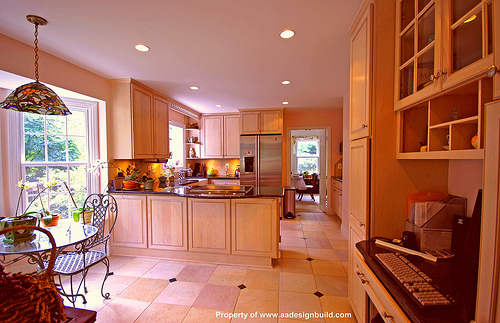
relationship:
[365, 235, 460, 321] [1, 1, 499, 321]
desk in kitchen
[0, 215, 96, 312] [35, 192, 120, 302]
table with chair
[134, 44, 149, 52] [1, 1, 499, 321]
kitchen lighting in kitchen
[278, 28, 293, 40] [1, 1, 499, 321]
kitchen lighting in kitchen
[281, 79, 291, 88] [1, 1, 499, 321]
lighting in kitchen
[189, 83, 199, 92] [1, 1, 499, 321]
kitchen lighting in kitchen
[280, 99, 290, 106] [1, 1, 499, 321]
lighting in kitchen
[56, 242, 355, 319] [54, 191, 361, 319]
tiles on floor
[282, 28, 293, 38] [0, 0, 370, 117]
kitchen lighting in ceiling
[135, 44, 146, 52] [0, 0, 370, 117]
kitchen lighting in ceiling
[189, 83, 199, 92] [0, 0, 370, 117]
kitchen lighting in ceiling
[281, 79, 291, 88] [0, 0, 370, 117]
lighting in ceiling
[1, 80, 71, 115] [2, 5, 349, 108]
stained glass in ceiling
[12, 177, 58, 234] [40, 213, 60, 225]
flowers in pot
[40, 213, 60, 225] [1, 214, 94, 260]
pot on table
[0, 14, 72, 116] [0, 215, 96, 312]
lamp over table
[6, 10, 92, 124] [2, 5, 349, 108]
lamp hanging from ceiling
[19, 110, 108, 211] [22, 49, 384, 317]
patio door leading out to kitchen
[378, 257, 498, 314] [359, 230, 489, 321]
keyboard on desk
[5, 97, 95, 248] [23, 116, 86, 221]
window looking out on yard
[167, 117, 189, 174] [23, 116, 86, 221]
window looking out on yard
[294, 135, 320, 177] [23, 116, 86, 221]
window looking out on yard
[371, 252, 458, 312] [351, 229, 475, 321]
keyboard on desk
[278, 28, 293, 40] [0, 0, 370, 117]
kitchen lighting on ceiling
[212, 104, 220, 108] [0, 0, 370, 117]
kitchen lighting on ceiling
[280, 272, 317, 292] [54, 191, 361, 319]
tile on floor